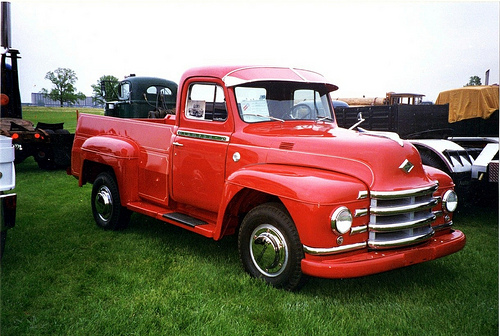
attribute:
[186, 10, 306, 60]
sky — white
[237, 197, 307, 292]
tire — front right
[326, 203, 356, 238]
headlight — front right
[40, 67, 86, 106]
tree — large, green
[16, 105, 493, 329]
field — green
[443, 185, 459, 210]
headlight — front right